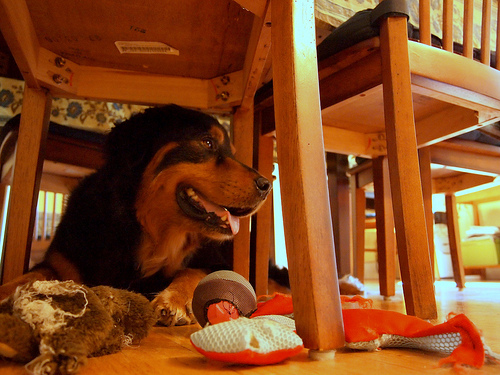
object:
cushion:
[315, 7, 485, 63]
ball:
[191, 269, 259, 327]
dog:
[0, 103, 284, 328]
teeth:
[186, 189, 199, 201]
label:
[115, 40, 179, 56]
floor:
[135, 324, 202, 374]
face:
[129, 112, 234, 223]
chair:
[252, 0, 499, 321]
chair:
[347, 120, 500, 302]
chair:
[0, 0, 349, 362]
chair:
[0, 115, 107, 235]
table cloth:
[0, 75, 229, 138]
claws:
[149, 300, 197, 328]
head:
[105, 101, 268, 244]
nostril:
[258, 183, 270, 192]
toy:
[188, 308, 499, 374]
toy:
[0, 280, 159, 375]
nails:
[160, 309, 167, 316]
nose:
[253, 176, 273, 194]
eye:
[200, 140, 212, 149]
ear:
[99, 103, 186, 157]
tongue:
[194, 190, 240, 235]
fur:
[55, 220, 173, 275]